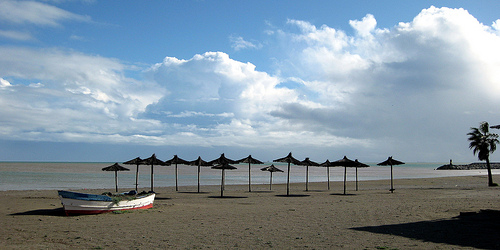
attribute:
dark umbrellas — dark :
[95, 141, 409, 206]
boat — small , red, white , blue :
[53, 182, 158, 217]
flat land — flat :
[435, 160, 492, 171]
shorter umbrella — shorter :
[240, 150, 304, 204]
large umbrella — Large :
[103, 160, 127, 199]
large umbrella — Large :
[131, 156, 147, 190]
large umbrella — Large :
[144, 150, 165, 209]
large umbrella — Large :
[182, 152, 207, 187]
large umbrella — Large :
[187, 150, 208, 198]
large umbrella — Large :
[207, 150, 231, 203]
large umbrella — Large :
[232, 153, 269, 199]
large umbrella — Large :
[256, 156, 283, 198]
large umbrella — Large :
[269, 145, 299, 199]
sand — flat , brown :
[4, 180, 498, 245]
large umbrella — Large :
[297, 156, 315, 194]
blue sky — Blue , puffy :
[4, 3, 498, 163]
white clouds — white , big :
[123, 30, 458, 133]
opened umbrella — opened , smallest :
[258, 163, 288, 193]